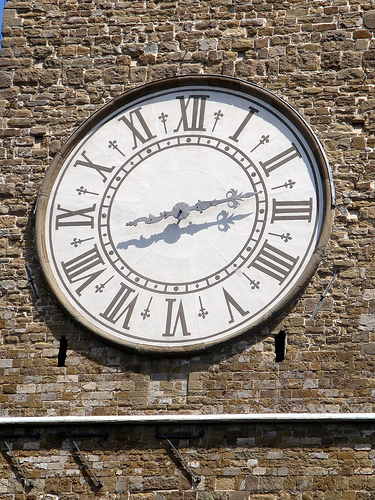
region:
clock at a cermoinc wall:
[11, 134, 326, 405]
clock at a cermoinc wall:
[61, 193, 348, 469]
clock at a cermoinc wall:
[31, 109, 312, 459]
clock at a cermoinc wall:
[18, 121, 339, 332]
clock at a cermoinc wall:
[34, 2, 269, 437]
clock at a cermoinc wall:
[27, 64, 306, 366]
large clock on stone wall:
[6, 43, 367, 378]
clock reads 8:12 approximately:
[6, 68, 346, 372]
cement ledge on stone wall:
[1, 392, 374, 471]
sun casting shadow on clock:
[92, 163, 284, 255]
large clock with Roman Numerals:
[0, 62, 371, 377]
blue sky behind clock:
[0, 1, 9, 48]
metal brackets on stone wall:
[0, 420, 246, 487]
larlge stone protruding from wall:
[82, 41, 173, 64]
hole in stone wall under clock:
[274, 324, 292, 378]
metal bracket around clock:
[277, 94, 337, 224]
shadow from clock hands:
[116, 205, 255, 250]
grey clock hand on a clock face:
[121, 184, 262, 235]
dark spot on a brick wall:
[275, 331, 298, 366]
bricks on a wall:
[215, 378, 263, 408]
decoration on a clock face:
[69, 183, 100, 203]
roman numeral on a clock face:
[61, 148, 117, 191]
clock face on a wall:
[13, 53, 351, 401]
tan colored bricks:
[103, 371, 207, 401]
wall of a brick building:
[28, 309, 56, 403]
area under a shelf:
[8, 437, 214, 491]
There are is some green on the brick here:
[324, 454, 332, 484]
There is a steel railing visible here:
[169, 449, 198, 477]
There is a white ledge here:
[320, 408, 330, 429]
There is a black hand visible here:
[160, 196, 183, 264]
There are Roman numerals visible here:
[164, 304, 184, 355]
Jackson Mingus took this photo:
[127, 210, 175, 370]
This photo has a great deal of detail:
[94, 299, 166, 447]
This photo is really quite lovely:
[148, 294, 203, 482]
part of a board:
[220, 409, 225, 434]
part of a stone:
[207, 434, 216, 489]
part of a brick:
[178, 445, 189, 466]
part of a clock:
[181, 358, 193, 381]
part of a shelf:
[197, 423, 203, 444]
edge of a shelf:
[180, 421, 188, 440]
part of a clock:
[195, 360, 197, 365]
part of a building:
[214, 433, 220, 441]